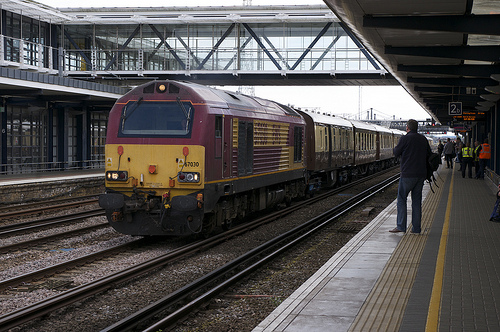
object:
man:
[386, 118, 442, 233]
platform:
[251, 150, 500, 331]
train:
[98, 78, 460, 238]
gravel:
[1, 237, 289, 310]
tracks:
[1, 140, 408, 331]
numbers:
[177, 159, 202, 169]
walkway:
[59, 4, 400, 88]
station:
[0, 2, 498, 331]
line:
[421, 160, 458, 331]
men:
[461, 141, 478, 180]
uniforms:
[460, 142, 493, 157]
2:
[449, 102, 459, 114]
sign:
[447, 98, 463, 117]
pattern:
[456, 208, 498, 281]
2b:
[448, 102, 464, 115]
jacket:
[478, 140, 493, 162]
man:
[474, 138, 495, 178]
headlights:
[174, 170, 203, 184]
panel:
[106, 144, 208, 199]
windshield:
[117, 98, 198, 140]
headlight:
[99, 170, 126, 180]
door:
[219, 114, 235, 180]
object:
[145, 165, 161, 176]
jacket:
[460, 144, 473, 162]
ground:
[0, 242, 271, 331]